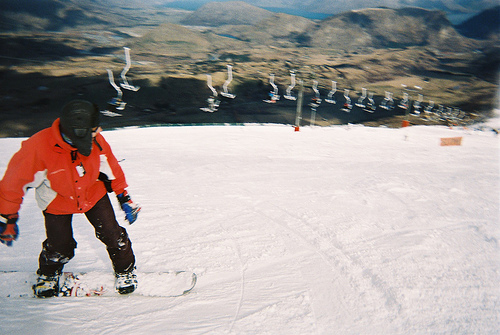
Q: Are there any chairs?
A: Yes, there is a chair.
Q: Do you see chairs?
A: Yes, there is a chair.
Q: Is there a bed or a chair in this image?
A: Yes, there is a chair.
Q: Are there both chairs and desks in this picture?
A: No, there is a chair but no desks.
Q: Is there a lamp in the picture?
A: No, there are no lamps.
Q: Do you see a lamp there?
A: No, there are no lamps.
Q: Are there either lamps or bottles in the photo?
A: No, there are no lamps or bottles.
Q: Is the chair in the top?
A: Yes, the chair is in the top of the image.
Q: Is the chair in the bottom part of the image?
A: No, the chair is in the top of the image.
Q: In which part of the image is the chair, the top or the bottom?
A: The chair is in the top of the image.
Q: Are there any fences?
A: No, there are no fences.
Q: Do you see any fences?
A: No, there are no fences.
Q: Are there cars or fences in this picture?
A: No, there are no fences or cars.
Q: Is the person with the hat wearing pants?
A: Yes, the person is wearing pants.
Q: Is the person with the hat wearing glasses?
A: No, the person is wearing pants.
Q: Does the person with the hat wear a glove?
A: Yes, the person wears a glove.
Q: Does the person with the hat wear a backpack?
A: No, the person wears a glove.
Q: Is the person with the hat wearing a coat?
A: Yes, the person is wearing a coat.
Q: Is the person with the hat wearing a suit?
A: No, the person is wearing a coat.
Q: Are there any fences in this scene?
A: No, there are no fences.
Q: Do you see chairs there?
A: Yes, there is a chair.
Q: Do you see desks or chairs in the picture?
A: Yes, there is a chair.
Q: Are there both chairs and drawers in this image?
A: No, there is a chair but no drawers.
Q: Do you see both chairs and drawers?
A: No, there is a chair but no drawers.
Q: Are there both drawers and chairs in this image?
A: No, there is a chair but no drawers.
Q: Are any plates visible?
A: No, there are no plates.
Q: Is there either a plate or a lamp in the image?
A: No, there are no plates or lamps.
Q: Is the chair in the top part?
A: Yes, the chair is in the top of the image.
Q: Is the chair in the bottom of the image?
A: No, the chair is in the top of the image.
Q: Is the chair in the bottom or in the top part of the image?
A: The chair is in the top of the image.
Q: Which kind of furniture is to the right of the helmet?
A: The piece of furniture is a chair.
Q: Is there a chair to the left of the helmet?
A: No, the chair is to the right of the helmet.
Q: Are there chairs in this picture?
A: Yes, there is a chair.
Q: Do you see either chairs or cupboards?
A: Yes, there is a chair.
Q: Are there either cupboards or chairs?
A: Yes, there is a chair.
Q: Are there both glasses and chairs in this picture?
A: No, there is a chair but no glasses.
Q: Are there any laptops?
A: No, there are no laptops.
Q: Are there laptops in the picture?
A: No, there are no laptops.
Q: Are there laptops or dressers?
A: No, there are no laptops or dressers.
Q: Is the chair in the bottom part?
A: No, the chair is in the top of the image.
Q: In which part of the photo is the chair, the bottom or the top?
A: The chair is in the top of the image.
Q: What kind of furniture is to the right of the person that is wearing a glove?
A: The piece of furniture is a chair.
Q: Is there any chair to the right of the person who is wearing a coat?
A: Yes, there is a chair to the right of the person.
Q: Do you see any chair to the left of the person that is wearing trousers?
A: No, the chair is to the right of the person.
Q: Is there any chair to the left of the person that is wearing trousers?
A: No, the chair is to the right of the person.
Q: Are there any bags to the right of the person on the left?
A: No, there is a chair to the right of the person.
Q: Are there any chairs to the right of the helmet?
A: Yes, there is a chair to the right of the helmet.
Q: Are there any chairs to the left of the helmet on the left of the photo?
A: No, the chair is to the right of the helmet.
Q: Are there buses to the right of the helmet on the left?
A: No, there is a chair to the right of the helmet.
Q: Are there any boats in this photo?
A: No, there are no boats.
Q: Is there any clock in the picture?
A: No, there are no clocks.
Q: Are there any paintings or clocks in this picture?
A: No, there are no clocks or paintings.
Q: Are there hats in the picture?
A: Yes, there is a hat.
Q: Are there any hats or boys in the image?
A: Yes, there is a hat.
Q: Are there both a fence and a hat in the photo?
A: No, there is a hat but no fences.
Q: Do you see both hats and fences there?
A: No, there is a hat but no fences.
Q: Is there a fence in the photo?
A: No, there are no fences.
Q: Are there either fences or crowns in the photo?
A: No, there are no fences or crowns.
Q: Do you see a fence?
A: No, there are no fences.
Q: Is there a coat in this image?
A: Yes, there is a coat.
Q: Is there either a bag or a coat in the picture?
A: Yes, there is a coat.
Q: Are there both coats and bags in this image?
A: No, there is a coat but no bags.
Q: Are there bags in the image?
A: No, there are no bags.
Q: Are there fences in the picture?
A: No, there are no fences.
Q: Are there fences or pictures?
A: No, there are no fences or pictures.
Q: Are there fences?
A: No, there are no fences.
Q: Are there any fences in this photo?
A: No, there are no fences.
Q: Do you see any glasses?
A: No, there are no glasses.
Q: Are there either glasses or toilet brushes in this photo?
A: No, there are no glasses or toilet brushes.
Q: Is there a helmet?
A: Yes, there is a helmet.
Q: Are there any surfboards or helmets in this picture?
A: Yes, there is a helmet.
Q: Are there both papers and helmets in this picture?
A: No, there is a helmet but no papers.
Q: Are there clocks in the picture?
A: No, there are no clocks.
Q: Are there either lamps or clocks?
A: No, there are no clocks or lamps.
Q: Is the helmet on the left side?
A: Yes, the helmet is on the left of the image.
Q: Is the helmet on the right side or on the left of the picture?
A: The helmet is on the left of the image.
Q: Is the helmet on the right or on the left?
A: The helmet is on the left of the image.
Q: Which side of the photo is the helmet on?
A: The helmet is on the left of the image.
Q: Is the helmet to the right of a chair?
A: No, the helmet is to the left of a chair.